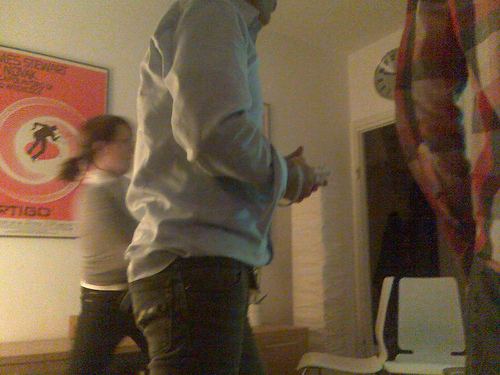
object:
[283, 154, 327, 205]
hand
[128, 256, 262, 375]
jeans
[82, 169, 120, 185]
collar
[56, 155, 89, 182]
ponytail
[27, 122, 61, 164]
silhouette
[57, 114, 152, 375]
girl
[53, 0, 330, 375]
couple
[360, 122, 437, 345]
door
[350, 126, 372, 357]
door facing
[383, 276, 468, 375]
chair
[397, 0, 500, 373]
man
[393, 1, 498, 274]
shirt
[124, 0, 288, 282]
shirt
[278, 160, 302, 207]
strap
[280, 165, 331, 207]
controller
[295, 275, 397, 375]
chair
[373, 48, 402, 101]
clock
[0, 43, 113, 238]
artwork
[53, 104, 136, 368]
person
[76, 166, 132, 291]
shirt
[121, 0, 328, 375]
man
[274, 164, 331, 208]
game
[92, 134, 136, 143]
glasses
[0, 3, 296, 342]
wall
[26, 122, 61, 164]
man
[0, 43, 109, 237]
picture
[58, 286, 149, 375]
jeans